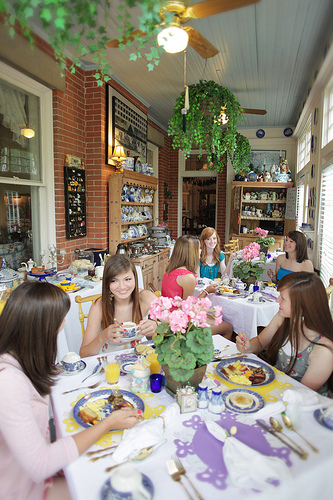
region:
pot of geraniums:
[139, 288, 222, 401]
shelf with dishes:
[108, 170, 165, 258]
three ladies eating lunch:
[3, 257, 328, 389]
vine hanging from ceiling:
[171, 74, 259, 181]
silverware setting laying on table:
[169, 416, 311, 485]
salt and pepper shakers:
[194, 379, 230, 420]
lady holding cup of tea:
[97, 261, 157, 347]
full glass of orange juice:
[101, 349, 122, 388]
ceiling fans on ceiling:
[100, 3, 266, 145]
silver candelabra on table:
[34, 237, 69, 281]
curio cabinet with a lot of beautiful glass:
[99, 162, 170, 251]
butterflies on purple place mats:
[149, 411, 292, 484]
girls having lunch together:
[12, 203, 317, 419]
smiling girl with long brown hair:
[89, 254, 152, 351]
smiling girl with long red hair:
[194, 223, 228, 271]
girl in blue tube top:
[262, 226, 314, 290]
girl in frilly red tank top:
[149, 232, 208, 304]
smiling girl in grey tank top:
[240, 249, 329, 410]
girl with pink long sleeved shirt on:
[0, 274, 84, 490]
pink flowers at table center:
[149, 286, 220, 413]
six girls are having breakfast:
[51, 225, 310, 425]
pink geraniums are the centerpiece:
[141, 287, 210, 388]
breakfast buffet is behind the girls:
[1, 240, 138, 306]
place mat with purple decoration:
[167, 410, 287, 484]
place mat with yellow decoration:
[205, 351, 283, 409]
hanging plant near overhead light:
[64, 0, 251, 66]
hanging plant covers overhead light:
[149, 61, 259, 177]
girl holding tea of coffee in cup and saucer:
[99, 312, 145, 342]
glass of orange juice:
[93, 353, 123, 388]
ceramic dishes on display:
[102, 172, 169, 252]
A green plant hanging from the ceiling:
[176, 78, 259, 160]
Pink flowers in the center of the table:
[147, 295, 222, 386]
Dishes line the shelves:
[112, 172, 164, 243]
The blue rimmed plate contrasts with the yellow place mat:
[213, 356, 291, 399]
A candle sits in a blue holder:
[147, 371, 169, 393]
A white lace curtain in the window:
[0, 81, 43, 155]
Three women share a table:
[168, 220, 321, 276]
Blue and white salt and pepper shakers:
[191, 378, 232, 413]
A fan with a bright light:
[93, 1, 267, 59]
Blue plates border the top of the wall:
[245, 122, 300, 138]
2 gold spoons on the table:
[263, 411, 324, 460]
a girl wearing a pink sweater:
[0, 283, 91, 498]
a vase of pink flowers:
[156, 292, 220, 392]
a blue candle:
[147, 371, 166, 394]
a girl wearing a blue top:
[198, 226, 226, 281]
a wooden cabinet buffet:
[104, 169, 169, 276]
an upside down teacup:
[57, 347, 86, 376]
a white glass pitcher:
[17, 256, 39, 281]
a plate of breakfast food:
[214, 352, 275, 390]